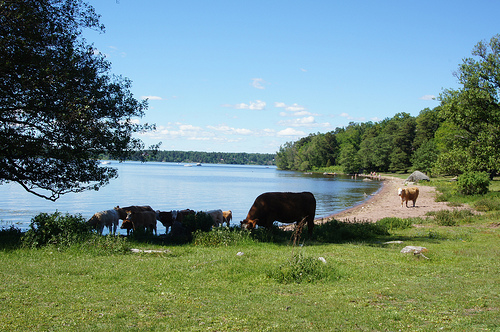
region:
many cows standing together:
[91, 198, 404, 234]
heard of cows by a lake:
[64, 173, 380, 244]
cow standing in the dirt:
[385, 178, 436, 225]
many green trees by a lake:
[301, 104, 498, 170]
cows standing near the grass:
[92, 201, 388, 297]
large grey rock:
[406, 165, 430, 183]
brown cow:
[232, 181, 323, 255]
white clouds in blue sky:
[180, 12, 247, 67]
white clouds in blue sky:
[297, 32, 338, 57]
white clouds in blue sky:
[360, 42, 394, 73]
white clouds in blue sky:
[215, 36, 269, 64]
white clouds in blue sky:
[290, 36, 328, 58]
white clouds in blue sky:
[162, 75, 197, 93]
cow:
[400, 179, 428, 213]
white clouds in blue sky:
[164, 63, 222, 117]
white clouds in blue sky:
[234, 65, 316, 107]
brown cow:
[234, 173, 315, 240]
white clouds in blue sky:
[151, 19, 175, 57]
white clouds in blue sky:
[150, 82, 201, 127]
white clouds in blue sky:
[280, 99, 317, 150]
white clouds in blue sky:
[290, 82, 314, 117]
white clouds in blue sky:
[184, 41, 266, 101]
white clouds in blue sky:
[148, 11, 180, 48]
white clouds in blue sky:
[208, 56, 255, 106]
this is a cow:
[66, 195, 123, 234]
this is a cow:
[119, 205, 159, 241]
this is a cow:
[119, 190, 156, 228]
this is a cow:
[151, 193, 192, 237]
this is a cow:
[181, 193, 238, 255]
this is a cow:
[236, 173, 319, 253]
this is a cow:
[390, 180, 435, 222]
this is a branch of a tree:
[41, 163, 94, 195]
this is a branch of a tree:
[50, 90, 146, 168]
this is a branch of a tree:
[336, 123, 390, 171]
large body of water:
[171, 164, 266, 193]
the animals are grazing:
[104, 194, 317, 241]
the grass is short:
[85, 262, 187, 303]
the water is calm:
[146, 160, 212, 192]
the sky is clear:
[251, 20, 348, 65]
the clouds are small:
[162, 93, 282, 144]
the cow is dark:
[264, 200, 314, 222]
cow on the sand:
[394, 168, 423, 216]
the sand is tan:
[377, 203, 392, 214]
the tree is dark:
[0, 68, 136, 190]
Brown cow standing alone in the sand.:
[396, 184, 421, 210]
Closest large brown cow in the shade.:
[235, 192, 320, 238]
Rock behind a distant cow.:
[407, 169, 436, 184]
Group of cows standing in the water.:
[85, 204, 234, 239]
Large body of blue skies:
[148, 13, 219, 73]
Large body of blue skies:
[282, 5, 395, 59]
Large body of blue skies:
[153, 7, 225, 67]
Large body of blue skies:
[131, 9, 223, 76]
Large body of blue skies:
[256, 12, 369, 72]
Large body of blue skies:
[137, 14, 233, 71]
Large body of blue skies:
[230, 18, 336, 81]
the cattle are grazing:
[88, 170, 371, 318]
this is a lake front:
[72, 120, 404, 310]